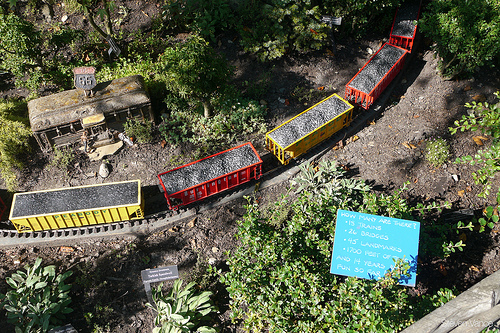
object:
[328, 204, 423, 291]
sign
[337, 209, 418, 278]
writing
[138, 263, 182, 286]
sign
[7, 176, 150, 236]
train car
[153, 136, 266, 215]
train car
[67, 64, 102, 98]
sign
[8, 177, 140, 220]
coal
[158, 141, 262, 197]
coal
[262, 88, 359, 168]
train car